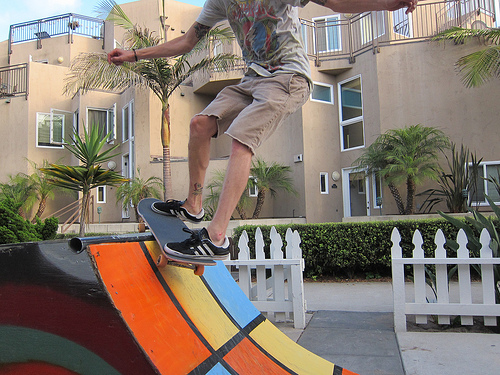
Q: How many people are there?
A: One.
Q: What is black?
A: Skateboard.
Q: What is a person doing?
A: Skateboarding.